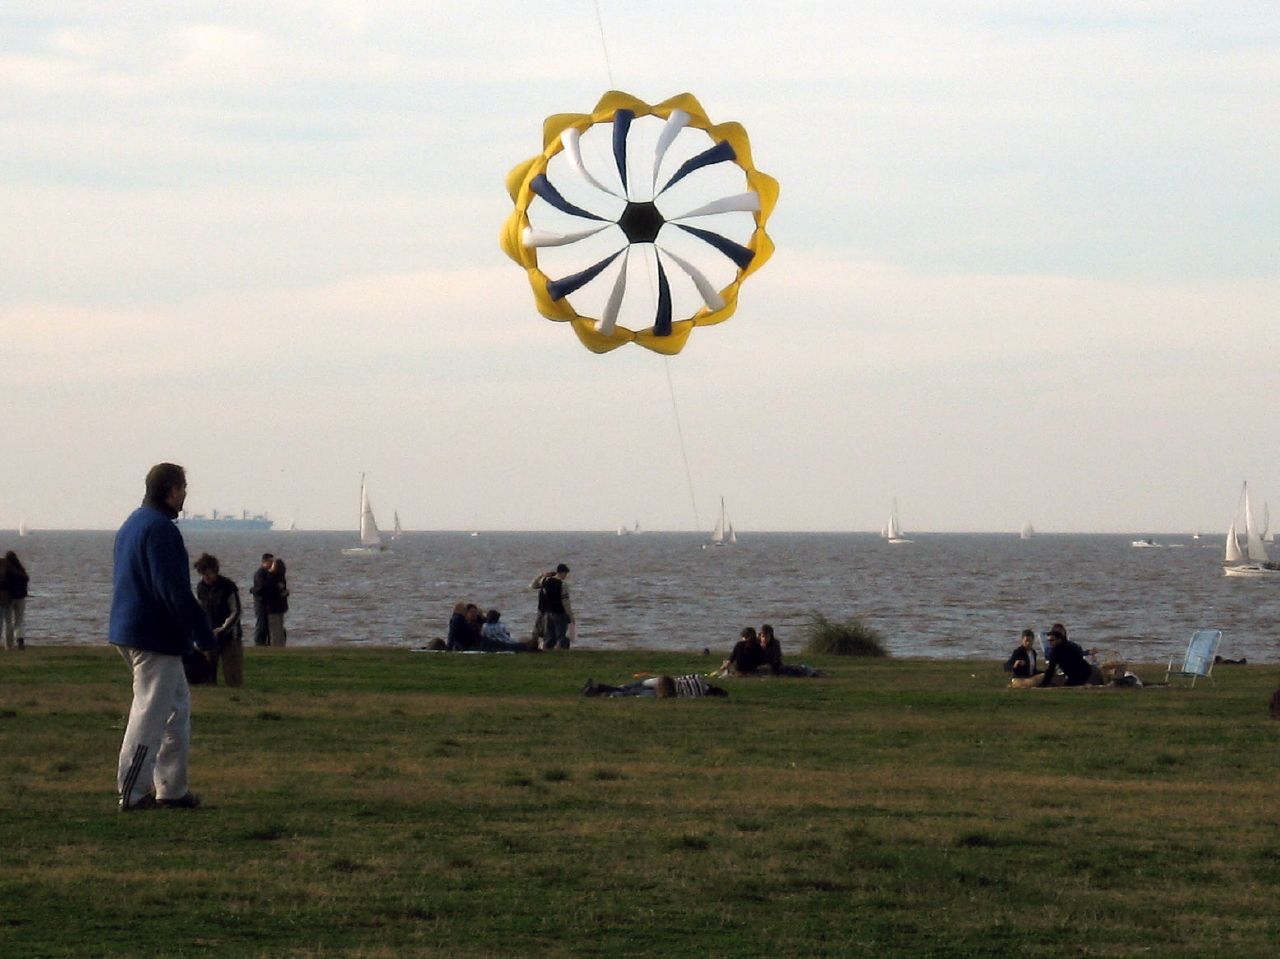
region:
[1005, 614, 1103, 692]
two people sitting on the ground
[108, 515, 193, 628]
a man wearing a blue jacket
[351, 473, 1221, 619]
a large body of water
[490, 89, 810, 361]
a round kite in the sky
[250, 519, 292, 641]
two people hugging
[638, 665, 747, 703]
a person laying on the grass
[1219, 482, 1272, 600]
a white boat in the water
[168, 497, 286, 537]
a large boat in the water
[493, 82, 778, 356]
the large black and yellow kite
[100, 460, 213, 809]
the man is wearing a blue jacket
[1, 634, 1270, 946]
the field is grassy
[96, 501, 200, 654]
the jacket is blue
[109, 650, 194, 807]
the sweatpants are grey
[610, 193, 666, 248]
the hectogon in the center of the kite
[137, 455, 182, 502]
the head of the man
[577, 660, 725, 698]
the person laying flat on the field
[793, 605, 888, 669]
the bush is in the field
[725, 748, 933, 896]
a view of ground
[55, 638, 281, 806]
legs of the person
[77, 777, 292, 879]
shoes of the person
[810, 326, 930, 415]
a view of clouds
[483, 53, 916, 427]
a view of wheel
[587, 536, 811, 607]
a view of water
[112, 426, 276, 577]
face of the person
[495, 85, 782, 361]
a yellow blue and white kite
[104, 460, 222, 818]
a man walking near the shore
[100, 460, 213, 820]
a man wearing a blue coat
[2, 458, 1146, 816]
people enjoying themselves on a shore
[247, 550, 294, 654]
a couple embracing on a shore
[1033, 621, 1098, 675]
a woman sitting in a chair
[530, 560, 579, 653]
a couple walking along a shore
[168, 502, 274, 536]
a cargo ship in the distance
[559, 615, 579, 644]
a man carrying a plastic bag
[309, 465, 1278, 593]
sail boats on the water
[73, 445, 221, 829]
a man wearing a blue jacket and white pants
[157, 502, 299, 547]
a large ship on the horizon to the left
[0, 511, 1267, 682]
a large body of water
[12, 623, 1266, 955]
a grassy shoreline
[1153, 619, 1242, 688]
a blue chair sitting to the right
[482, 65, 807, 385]
A yellow, white and black kite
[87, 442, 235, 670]
A man wearing a blue coat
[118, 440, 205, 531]
The man has dark hair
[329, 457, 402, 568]
A white sail on a boat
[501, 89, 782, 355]
a round kite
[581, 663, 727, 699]
a person laying in the grass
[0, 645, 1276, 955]
a grassy field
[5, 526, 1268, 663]
a large body of water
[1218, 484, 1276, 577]
a sail boat on the water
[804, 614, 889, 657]
a small bush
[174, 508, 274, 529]
a large distant ship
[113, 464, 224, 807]
a man walking in the grass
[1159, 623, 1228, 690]
a folding lawn chair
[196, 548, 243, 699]
a boy kneeling in grass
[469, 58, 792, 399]
kite is in the air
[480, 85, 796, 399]
kite has a yellow border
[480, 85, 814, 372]
kite has black and silver blades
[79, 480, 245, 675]
man is wearing a coat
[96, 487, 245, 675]
coat is blue in color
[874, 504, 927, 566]
sailboat is white in colo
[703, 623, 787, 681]
person sitting on grass